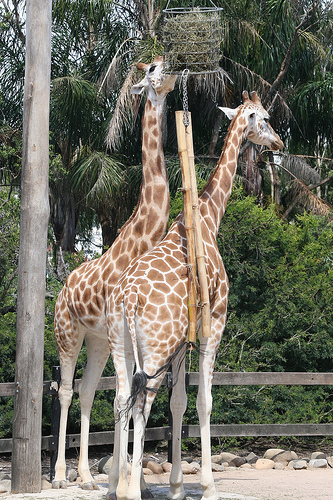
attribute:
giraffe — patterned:
[104, 89, 285, 498]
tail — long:
[119, 287, 148, 428]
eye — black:
[262, 117, 270, 125]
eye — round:
[147, 61, 156, 73]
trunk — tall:
[9, 0, 51, 495]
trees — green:
[0, 0, 331, 444]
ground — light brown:
[0, 439, 331, 498]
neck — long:
[133, 93, 172, 247]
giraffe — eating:
[150, 41, 226, 146]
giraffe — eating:
[115, 40, 193, 123]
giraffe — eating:
[136, 80, 206, 147]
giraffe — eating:
[102, 54, 222, 181]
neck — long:
[185, 127, 254, 246]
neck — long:
[174, 82, 288, 236]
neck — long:
[176, 115, 286, 208]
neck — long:
[191, 104, 272, 229]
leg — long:
[42, 310, 121, 441]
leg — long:
[92, 344, 188, 462]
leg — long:
[84, 374, 153, 484]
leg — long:
[165, 331, 281, 453]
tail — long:
[108, 262, 179, 413]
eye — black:
[252, 107, 287, 144]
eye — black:
[115, 55, 173, 78]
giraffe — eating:
[122, 34, 201, 119]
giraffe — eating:
[131, 30, 205, 148]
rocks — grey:
[233, 457, 306, 475]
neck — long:
[104, 82, 208, 232]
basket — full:
[142, 10, 197, 56]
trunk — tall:
[11, 40, 168, 404]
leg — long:
[165, 369, 242, 473]